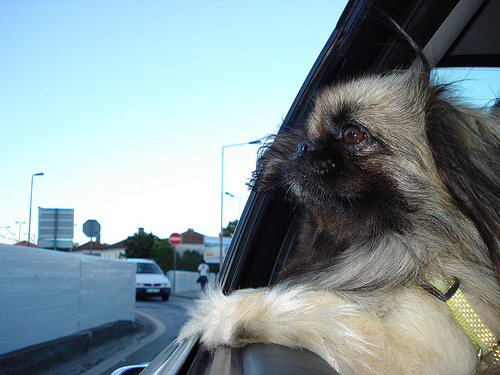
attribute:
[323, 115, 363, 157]
eye — brown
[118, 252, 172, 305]
van — white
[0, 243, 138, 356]
wall — white 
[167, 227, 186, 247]
sign —  white 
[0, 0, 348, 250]
sky — dusk 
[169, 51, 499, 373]
dog — black, white